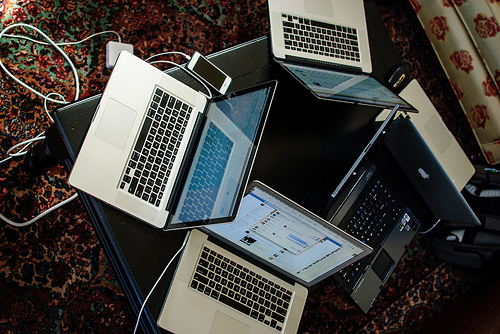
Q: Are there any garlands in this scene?
A: No, there are no garlands.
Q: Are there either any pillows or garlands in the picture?
A: No, there are no garlands or pillows.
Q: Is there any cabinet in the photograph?
A: No, there are no cabinets.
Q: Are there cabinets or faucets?
A: No, there are no cabinets or faucets.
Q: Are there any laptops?
A: Yes, there is a laptop.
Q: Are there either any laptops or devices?
A: Yes, there is a laptop.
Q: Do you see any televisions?
A: No, there are no televisions.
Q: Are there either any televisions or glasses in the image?
A: No, there are no televisions or glasses.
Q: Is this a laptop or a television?
A: This is a laptop.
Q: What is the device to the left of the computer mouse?
A: The device is a laptop.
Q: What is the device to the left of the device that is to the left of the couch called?
A: The device is a laptop.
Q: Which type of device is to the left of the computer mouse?
A: The device is a laptop.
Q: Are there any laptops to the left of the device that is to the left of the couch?
A: Yes, there is a laptop to the left of the mouse.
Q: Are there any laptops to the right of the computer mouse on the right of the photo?
A: No, the laptop is to the left of the mouse.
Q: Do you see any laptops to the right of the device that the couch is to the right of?
A: No, the laptop is to the left of the mouse.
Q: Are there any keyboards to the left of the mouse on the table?
A: No, there is a laptop to the left of the computer mouse.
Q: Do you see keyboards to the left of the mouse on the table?
A: No, there is a laptop to the left of the computer mouse.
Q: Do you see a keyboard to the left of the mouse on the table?
A: No, there is a laptop to the left of the computer mouse.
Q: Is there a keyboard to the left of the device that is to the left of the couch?
A: No, there is a laptop to the left of the computer mouse.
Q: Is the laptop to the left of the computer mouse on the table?
A: Yes, the laptop is to the left of the computer mouse.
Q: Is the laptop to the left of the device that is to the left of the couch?
A: Yes, the laptop is to the left of the computer mouse.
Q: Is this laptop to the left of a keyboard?
A: No, the laptop is to the left of the computer mouse.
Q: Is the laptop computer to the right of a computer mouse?
A: No, the laptop computer is to the left of a computer mouse.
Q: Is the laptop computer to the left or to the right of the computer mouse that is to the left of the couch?
A: The laptop computer is to the left of the mouse.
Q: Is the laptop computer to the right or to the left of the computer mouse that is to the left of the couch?
A: The laptop computer is to the left of the mouse.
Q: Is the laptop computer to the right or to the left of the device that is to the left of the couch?
A: The laptop computer is to the left of the mouse.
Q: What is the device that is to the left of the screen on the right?
A: The device is a laptop.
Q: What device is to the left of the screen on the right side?
A: The device is a laptop.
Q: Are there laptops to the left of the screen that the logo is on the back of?
A: Yes, there is a laptop to the left of the screen.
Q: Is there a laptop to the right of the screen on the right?
A: No, the laptop is to the left of the screen.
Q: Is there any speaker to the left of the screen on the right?
A: No, there is a laptop to the left of the screen.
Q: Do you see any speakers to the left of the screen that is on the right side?
A: No, there is a laptop to the left of the screen.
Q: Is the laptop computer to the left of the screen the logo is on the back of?
A: Yes, the laptop computer is to the left of the screen.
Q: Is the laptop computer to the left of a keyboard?
A: No, the laptop computer is to the left of the screen.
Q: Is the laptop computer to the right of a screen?
A: No, the laptop computer is to the left of a screen.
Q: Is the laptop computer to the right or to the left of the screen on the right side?
A: The laptop computer is to the left of the screen.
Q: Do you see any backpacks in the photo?
A: Yes, there is a backpack.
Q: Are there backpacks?
A: Yes, there is a backpack.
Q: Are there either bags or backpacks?
A: Yes, there is a backpack.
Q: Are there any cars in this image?
A: No, there are no cars.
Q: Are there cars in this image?
A: No, there are no cars.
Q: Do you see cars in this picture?
A: No, there are no cars.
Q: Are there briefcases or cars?
A: No, there are no cars or briefcases.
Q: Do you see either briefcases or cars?
A: No, there are no cars or briefcases.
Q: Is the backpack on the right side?
A: Yes, the backpack is on the right of the image.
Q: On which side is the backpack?
A: The backpack is on the right of the image.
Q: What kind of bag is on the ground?
A: The bag is a backpack.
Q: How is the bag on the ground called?
A: The bag is a backpack.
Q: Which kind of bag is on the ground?
A: The bag is a backpack.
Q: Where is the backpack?
A: The backpack is on the ground.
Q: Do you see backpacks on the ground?
A: Yes, there is a backpack on the ground.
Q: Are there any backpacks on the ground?
A: Yes, there is a backpack on the ground.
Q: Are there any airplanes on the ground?
A: No, there is a backpack on the ground.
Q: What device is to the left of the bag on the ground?
A: The device is a screen.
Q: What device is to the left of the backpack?
A: The device is a screen.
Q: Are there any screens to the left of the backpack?
A: Yes, there is a screen to the left of the backpack.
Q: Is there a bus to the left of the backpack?
A: No, there is a screen to the left of the backpack.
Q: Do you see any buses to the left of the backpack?
A: No, there is a screen to the left of the backpack.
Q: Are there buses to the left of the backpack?
A: No, there is a screen to the left of the backpack.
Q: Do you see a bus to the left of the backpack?
A: No, there is a screen to the left of the backpack.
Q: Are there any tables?
A: Yes, there is a table.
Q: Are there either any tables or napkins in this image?
A: Yes, there is a table.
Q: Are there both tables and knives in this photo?
A: No, there is a table but no knives.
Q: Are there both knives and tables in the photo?
A: No, there is a table but no knives.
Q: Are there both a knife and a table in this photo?
A: No, there is a table but no knives.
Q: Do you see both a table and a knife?
A: No, there is a table but no knives.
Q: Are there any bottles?
A: No, there are no bottles.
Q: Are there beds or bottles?
A: No, there are no bottles or beds.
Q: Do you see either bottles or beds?
A: No, there are no bottles or beds.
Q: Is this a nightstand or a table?
A: This is a table.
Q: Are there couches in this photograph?
A: Yes, there is a couch.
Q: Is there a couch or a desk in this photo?
A: Yes, there is a couch.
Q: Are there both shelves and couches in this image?
A: No, there is a couch but no shelves.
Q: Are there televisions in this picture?
A: No, there are no televisions.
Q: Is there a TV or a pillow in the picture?
A: No, there are no televisions or pillows.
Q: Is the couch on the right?
A: Yes, the couch is on the right of the image.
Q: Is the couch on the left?
A: No, the couch is on the right of the image.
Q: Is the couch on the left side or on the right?
A: The couch is on the right of the image.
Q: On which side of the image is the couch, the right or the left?
A: The couch is on the right of the image.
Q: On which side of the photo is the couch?
A: The couch is on the right of the image.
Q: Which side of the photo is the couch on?
A: The couch is on the right of the image.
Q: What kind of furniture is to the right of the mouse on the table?
A: The piece of furniture is a couch.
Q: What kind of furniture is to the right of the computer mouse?
A: The piece of furniture is a couch.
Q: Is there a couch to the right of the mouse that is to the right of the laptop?
A: Yes, there is a couch to the right of the computer mouse.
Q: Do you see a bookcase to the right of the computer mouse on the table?
A: No, there is a couch to the right of the computer mouse.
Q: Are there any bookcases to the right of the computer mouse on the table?
A: No, there is a couch to the right of the computer mouse.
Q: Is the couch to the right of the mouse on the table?
A: Yes, the couch is to the right of the mouse.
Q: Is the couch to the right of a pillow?
A: No, the couch is to the right of the mouse.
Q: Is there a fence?
A: No, there are no fences.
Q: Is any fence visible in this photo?
A: No, there are no fences.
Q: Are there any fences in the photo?
A: No, there are no fences.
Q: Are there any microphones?
A: No, there are no microphones.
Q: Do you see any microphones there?
A: No, there are no microphones.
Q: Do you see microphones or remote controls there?
A: No, there are no microphones or remote controls.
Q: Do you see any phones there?
A: Yes, there is a phone.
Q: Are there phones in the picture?
A: Yes, there is a phone.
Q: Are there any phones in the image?
A: Yes, there is a phone.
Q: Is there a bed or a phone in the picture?
A: Yes, there is a phone.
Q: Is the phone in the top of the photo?
A: Yes, the phone is in the top of the image.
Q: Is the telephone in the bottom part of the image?
A: No, the telephone is in the top of the image.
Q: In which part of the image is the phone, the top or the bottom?
A: The phone is in the top of the image.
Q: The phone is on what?
A: The phone is on the table.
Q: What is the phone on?
A: The phone is on the table.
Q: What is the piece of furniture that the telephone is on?
A: The piece of furniture is a table.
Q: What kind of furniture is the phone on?
A: The telephone is on the table.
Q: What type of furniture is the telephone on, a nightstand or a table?
A: The telephone is on a table.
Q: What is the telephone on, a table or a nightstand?
A: The telephone is on a table.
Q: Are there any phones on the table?
A: Yes, there is a phone on the table.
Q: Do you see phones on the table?
A: Yes, there is a phone on the table.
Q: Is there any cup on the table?
A: No, there is a phone on the table.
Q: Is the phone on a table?
A: Yes, the phone is on a table.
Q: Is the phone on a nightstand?
A: No, the phone is on a table.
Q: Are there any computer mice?
A: Yes, there is a computer mouse.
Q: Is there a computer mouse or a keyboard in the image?
A: Yes, there is a computer mouse.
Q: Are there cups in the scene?
A: No, there are no cups.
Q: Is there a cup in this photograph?
A: No, there are no cups.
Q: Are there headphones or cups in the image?
A: No, there are no cups or headphones.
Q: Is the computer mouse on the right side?
A: Yes, the computer mouse is on the right of the image.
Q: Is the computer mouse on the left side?
A: No, the computer mouse is on the right of the image.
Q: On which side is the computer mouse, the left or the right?
A: The computer mouse is on the right of the image.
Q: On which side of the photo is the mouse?
A: The mouse is on the right of the image.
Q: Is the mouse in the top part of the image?
A: Yes, the mouse is in the top of the image.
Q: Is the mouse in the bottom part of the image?
A: No, the mouse is in the top of the image.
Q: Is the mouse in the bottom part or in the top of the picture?
A: The mouse is in the top of the image.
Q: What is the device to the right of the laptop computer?
A: The device is a computer mouse.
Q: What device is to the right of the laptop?
A: The device is a computer mouse.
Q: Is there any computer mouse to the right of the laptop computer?
A: Yes, there is a computer mouse to the right of the laptop computer.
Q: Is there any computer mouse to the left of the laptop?
A: No, the computer mouse is to the right of the laptop.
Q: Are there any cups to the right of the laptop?
A: No, there is a computer mouse to the right of the laptop.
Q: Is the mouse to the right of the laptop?
A: Yes, the mouse is to the right of the laptop.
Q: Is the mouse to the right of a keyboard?
A: No, the mouse is to the right of the laptop.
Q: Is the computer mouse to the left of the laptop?
A: No, the computer mouse is to the right of the laptop.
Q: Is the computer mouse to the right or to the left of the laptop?
A: The computer mouse is to the right of the laptop.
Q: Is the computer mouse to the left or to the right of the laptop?
A: The computer mouse is to the right of the laptop.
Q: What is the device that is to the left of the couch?
A: The device is a computer mouse.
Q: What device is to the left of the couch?
A: The device is a computer mouse.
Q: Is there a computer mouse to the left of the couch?
A: Yes, there is a computer mouse to the left of the couch.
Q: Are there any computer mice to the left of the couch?
A: Yes, there is a computer mouse to the left of the couch.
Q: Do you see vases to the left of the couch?
A: No, there is a computer mouse to the left of the couch.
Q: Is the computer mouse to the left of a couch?
A: Yes, the computer mouse is to the left of a couch.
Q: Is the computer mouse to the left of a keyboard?
A: No, the computer mouse is to the left of a couch.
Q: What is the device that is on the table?
A: The device is a computer mouse.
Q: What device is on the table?
A: The device is a computer mouse.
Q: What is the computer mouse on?
A: The computer mouse is on the table.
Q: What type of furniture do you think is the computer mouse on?
A: The computer mouse is on the table.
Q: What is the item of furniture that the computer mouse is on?
A: The piece of furniture is a table.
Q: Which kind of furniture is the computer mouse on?
A: The computer mouse is on the table.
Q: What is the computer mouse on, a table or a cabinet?
A: The computer mouse is on a table.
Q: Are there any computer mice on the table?
A: Yes, there is a computer mouse on the table.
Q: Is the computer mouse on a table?
A: Yes, the computer mouse is on a table.